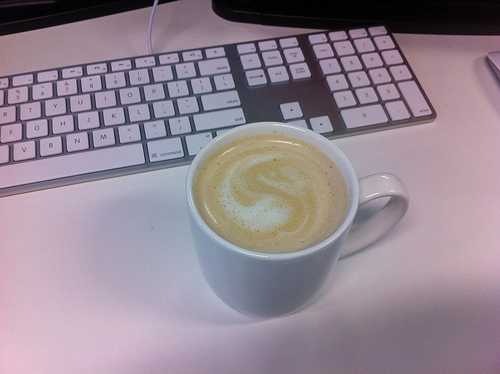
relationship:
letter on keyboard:
[45, 139, 55, 155] [1, 24, 436, 199]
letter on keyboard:
[55, 114, 66, 131] [1, 24, 436, 199]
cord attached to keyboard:
[145, 0, 158, 55] [1, 24, 436, 199]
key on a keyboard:
[336, 84, 359, 106] [303, 21, 412, 120]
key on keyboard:
[8, 84, 37, 102] [1, 24, 436, 199]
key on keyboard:
[29, 80, 59, 101] [1, 24, 436, 199]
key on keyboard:
[58, 77, 76, 97] [1, 24, 436, 199]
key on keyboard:
[128, 67, 152, 88] [0, 10, 446, 195]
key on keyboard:
[148, 62, 173, 82] [0, 19, 439, 213]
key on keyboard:
[175, 57, 195, 84] [1, 24, 436, 199]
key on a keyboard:
[242, 67, 267, 86] [1, 24, 436, 199]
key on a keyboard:
[288, 58, 311, 80] [1, 24, 436, 199]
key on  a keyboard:
[346, 70, 371, 90] [1, 24, 436, 199]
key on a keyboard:
[79, 72, 104, 92] [1, 24, 436, 199]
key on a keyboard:
[104, 69, 127, 89] [1, 24, 436, 199]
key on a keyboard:
[194, 55, 233, 78] [1, 24, 436, 199]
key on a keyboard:
[199, 89, 243, 110] [1, 24, 436, 199]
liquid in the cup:
[194, 129, 346, 250] [184, 119, 411, 319]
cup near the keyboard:
[183, 119, 407, 301] [1, 24, 436, 199]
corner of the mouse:
[482, 51, 484, 66] [479, 54, 485, 62]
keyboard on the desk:
[1, 24, 436, 199] [17, 8, 484, 358]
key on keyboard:
[7, 65, 36, 88] [1, 24, 436, 199]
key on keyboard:
[34, 70, 61, 83] [1, 24, 436, 199]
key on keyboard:
[61, 62, 82, 80] [0, 11, 408, 204]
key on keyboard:
[87, 59, 107, 83] [0, 22, 448, 187]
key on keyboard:
[110, 57, 134, 73] [0, 11, 408, 204]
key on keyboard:
[114, 61, 133, 73] [1, 24, 436, 199]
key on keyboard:
[155, 48, 181, 63] [0, 18, 465, 203]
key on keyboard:
[182, 49, 206, 66] [1, 24, 436, 199]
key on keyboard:
[202, 42, 226, 58] [1, 24, 436, 199]